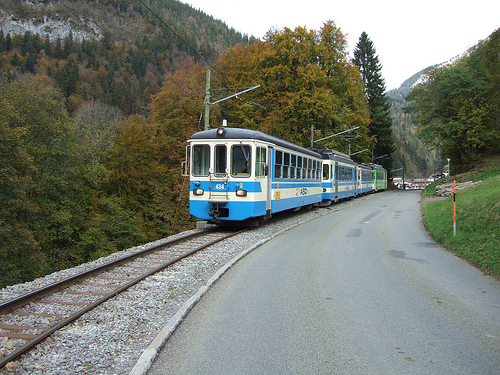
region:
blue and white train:
[154, 137, 396, 239]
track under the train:
[133, 223, 229, 289]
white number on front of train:
[204, 175, 233, 199]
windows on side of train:
[271, 151, 331, 187]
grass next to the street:
[463, 190, 491, 222]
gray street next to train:
[278, 241, 365, 298]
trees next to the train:
[5, 113, 149, 213]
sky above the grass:
[392, 21, 446, 65]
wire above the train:
[158, 25, 208, 90]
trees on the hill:
[126, 0, 238, 59]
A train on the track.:
[186, 121, 370, 214]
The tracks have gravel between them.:
[28, 255, 174, 335]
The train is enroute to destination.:
[188, 115, 397, 220]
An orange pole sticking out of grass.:
[443, 174, 470, 241]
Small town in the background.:
[389, 155, 440, 195]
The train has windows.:
[273, 153, 334, 178]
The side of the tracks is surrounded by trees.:
[22, 123, 164, 224]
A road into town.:
[275, 202, 444, 354]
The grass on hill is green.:
[461, 185, 496, 245]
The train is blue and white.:
[194, 126, 331, 219]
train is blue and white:
[189, 143, 375, 224]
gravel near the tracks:
[71, 267, 165, 366]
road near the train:
[243, 199, 480, 367]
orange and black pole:
[450, 168, 462, 236]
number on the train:
[208, 176, 229, 190]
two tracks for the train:
[0, 248, 182, 347]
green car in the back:
[371, 168, 392, 191]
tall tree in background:
[358, 43, 396, 157]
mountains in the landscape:
[391, 54, 458, 170]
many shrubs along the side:
[1, 64, 181, 229]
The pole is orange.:
[450, 180, 459, 236]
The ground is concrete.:
[287, 289, 336, 342]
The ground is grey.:
[266, 292, 300, 345]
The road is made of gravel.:
[81, 315, 123, 341]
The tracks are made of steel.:
[48, 314, 72, 337]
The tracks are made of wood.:
[42, 295, 81, 308]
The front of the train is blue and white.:
[194, 132, 251, 215]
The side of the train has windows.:
[277, 153, 319, 188]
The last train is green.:
[378, 172, 388, 187]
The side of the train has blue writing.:
[291, 186, 318, 195]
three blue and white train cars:
[175, 124, 376, 224]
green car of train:
[371, 162, 390, 200]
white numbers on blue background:
[208, 181, 226, 190]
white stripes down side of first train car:
[250, 181, 325, 206]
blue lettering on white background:
[292, 181, 312, 195]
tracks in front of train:
[5, 222, 223, 374]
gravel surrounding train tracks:
[10, 223, 248, 374]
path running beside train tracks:
[212, 168, 495, 372]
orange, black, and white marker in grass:
[445, 176, 462, 233]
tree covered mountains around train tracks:
[7, 10, 488, 193]